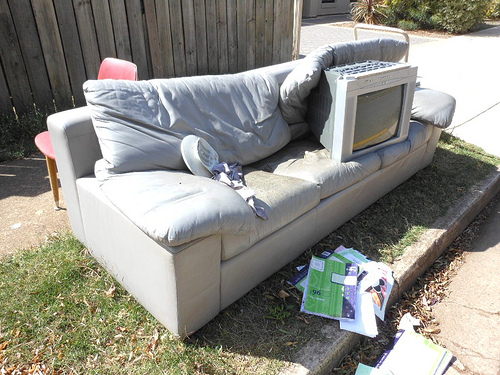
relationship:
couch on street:
[46, 57, 455, 342] [0, 27, 499, 373]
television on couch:
[305, 59, 420, 164] [46, 57, 455, 342]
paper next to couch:
[300, 253, 358, 321] [46, 57, 455, 342]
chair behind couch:
[35, 57, 138, 208] [46, 57, 455, 342]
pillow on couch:
[83, 75, 290, 174] [46, 57, 455, 342]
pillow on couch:
[278, 36, 411, 136] [46, 57, 455, 342]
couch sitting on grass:
[46, 57, 455, 342] [0, 130, 499, 375]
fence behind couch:
[0, 0, 294, 126] [46, 57, 455, 342]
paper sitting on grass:
[300, 253, 358, 321] [0, 130, 499, 375]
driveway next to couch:
[301, 16, 500, 132] [46, 57, 455, 342]